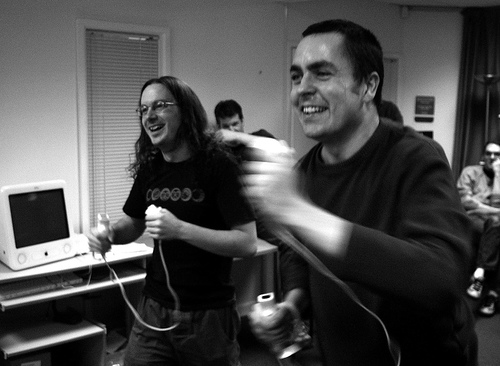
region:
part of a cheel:
[326, 79, 344, 124]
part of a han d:
[339, 268, 386, 293]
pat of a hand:
[171, 170, 232, 299]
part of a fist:
[139, 195, 176, 271]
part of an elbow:
[215, 225, 262, 272]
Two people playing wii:
[83, 24, 468, 362]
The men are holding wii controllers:
[89, 23, 479, 358]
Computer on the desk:
[1, 177, 91, 269]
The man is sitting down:
[455, 138, 497, 323]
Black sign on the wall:
[412, 91, 438, 122]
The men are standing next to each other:
[91, 23, 471, 363]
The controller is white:
[247, 289, 306, 356]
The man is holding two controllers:
[98, 69, 261, 359]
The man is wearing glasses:
[130, 80, 207, 156]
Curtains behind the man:
[451, 20, 498, 179]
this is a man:
[268, 23, 431, 318]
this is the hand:
[231, 138, 325, 235]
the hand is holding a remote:
[223, 288, 301, 358]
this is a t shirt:
[383, 153, 439, 225]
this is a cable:
[318, 270, 355, 296]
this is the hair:
[183, 105, 206, 140]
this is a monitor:
[10, 182, 66, 252]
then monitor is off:
[2, 184, 65, 248]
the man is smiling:
[143, 118, 170, 132]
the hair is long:
[185, 107, 207, 135]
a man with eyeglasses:
[100, 63, 205, 167]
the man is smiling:
[262, 29, 372, 171]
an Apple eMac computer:
[0, 178, 77, 270]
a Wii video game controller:
[94, 201, 182, 331]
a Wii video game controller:
[244, 135, 402, 364]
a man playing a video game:
[88, 75, 259, 365]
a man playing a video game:
[238, 18, 473, 364]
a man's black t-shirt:
[277, 114, 477, 364]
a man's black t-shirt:
[126, 138, 257, 305]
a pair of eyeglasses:
[133, 100, 178, 118]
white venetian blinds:
[86, 27, 161, 232]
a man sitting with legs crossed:
[456, 140, 496, 315]